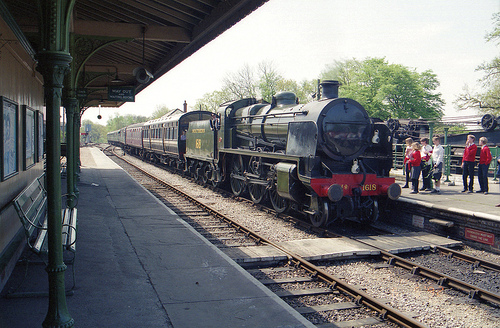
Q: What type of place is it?
A: It is a station.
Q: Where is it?
A: This is at the station.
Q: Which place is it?
A: It is a station.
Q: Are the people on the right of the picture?
A: Yes, the people are on the right of the image.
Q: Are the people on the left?
A: No, the people are on the right of the image.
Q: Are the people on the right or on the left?
A: The people are on the right of the image.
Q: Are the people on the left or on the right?
A: The people are on the right of the image.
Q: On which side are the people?
A: The people are on the right of the image.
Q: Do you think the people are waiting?
A: Yes, the people are waiting.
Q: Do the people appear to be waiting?
A: Yes, the people are waiting.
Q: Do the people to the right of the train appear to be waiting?
A: Yes, the people are waiting.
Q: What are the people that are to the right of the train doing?
A: The people are waiting.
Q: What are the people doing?
A: The people are waiting.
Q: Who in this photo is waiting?
A: The people are waiting.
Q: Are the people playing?
A: No, the people are waiting.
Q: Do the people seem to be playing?
A: No, the people are waiting.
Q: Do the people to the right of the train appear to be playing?
A: No, the people are waiting.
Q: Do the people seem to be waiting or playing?
A: The people are waiting.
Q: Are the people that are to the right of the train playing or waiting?
A: The people are waiting.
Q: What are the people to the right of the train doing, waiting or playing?
A: The people are waiting.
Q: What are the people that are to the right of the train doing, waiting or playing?
A: The people are waiting.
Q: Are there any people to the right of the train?
A: Yes, there are people to the right of the train.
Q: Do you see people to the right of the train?
A: Yes, there are people to the right of the train.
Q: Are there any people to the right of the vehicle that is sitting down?
A: Yes, there are people to the right of the train.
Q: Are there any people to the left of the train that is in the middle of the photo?
A: No, the people are to the right of the train.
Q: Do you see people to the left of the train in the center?
A: No, the people are to the right of the train.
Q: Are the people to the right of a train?
A: Yes, the people are to the right of a train.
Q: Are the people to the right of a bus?
A: No, the people are to the right of a train.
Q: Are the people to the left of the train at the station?
A: No, the people are to the right of the train.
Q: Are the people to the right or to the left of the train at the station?
A: The people are to the right of the train.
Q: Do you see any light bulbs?
A: No, there are no light bulbs.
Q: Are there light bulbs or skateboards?
A: No, there are no light bulbs or skateboards.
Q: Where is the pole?
A: The pole is at the station.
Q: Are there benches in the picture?
A: Yes, there is a bench.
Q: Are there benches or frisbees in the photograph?
A: Yes, there is a bench.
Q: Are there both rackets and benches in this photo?
A: No, there is a bench but no rackets.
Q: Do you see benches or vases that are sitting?
A: Yes, the bench is sitting.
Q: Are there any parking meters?
A: No, there are no parking meters.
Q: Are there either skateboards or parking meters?
A: No, there are no parking meters or skateboards.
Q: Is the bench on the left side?
A: Yes, the bench is on the left of the image.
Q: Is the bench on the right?
A: No, the bench is on the left of the image.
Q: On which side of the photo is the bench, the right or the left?
A: The bench is on the left of the image.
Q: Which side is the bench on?
A: The bench is on the left of the image.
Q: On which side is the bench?
A: The bench is on the left of the image.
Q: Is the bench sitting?
A: Yes, the bench is sitting.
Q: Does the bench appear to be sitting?
A: Yes, the bench is sitting.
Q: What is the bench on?
A: The bench is on the platform.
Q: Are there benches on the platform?
A: Yes, there is a bench on the platform.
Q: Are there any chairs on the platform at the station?
A: No, there is a bench on the platform.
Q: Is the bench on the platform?
A: Yes, the bench is on the platform.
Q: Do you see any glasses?
A: No, there are no glasses.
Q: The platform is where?
A: The platform is at the station.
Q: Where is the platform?
A: The platform is at the station.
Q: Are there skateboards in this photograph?
A: No, there are no skateboards.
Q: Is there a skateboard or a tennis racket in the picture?
A: No, there are no skateboards or rackets.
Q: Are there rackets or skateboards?
A: No, there are no skateboards or rackets.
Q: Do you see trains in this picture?
A: Yes, there is a train.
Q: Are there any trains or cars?
A: Yes, there is a train.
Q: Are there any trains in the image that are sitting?
A: Yes, there is a train that is sitting.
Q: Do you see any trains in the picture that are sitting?
A: Yes, there is a train that is sitting.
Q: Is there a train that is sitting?
A: Yes, there is a train that is sitting.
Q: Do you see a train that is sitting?
A: Yes, there is a train that is sitting.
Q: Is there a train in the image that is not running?
A: Yes, there is a train that is sitting.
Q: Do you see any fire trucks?
A: No, there are no fire trucks.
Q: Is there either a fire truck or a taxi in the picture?
A: No, there are no fire trucks or taxis.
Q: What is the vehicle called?
A: The vehicle is a train.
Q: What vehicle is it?
A: The vehicle is a train.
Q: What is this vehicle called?
A: This is a train.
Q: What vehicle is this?
A: This is a train.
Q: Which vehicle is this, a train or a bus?
A: This is a train.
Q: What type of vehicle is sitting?
A: The vehicle is a train.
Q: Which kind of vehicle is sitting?
A: The vehicle is a train.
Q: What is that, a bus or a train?
A: That is a train.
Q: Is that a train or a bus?
A: That is a train.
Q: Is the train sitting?
A: Yes, the train is sitting.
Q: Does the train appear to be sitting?
A: Yes, the train is sitting.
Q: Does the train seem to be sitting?
A: Yes, the train is sitting.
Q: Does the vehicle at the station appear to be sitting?
A: Yes, the train is sitting.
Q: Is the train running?
A: No, the train is sitting.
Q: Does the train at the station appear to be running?
A: No, the train is sitting.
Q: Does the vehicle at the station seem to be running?
A: No, the train is sitting.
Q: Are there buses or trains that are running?
A: No, there is a train but it is sitting.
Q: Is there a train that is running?
A: No, there is a train but it is sitting.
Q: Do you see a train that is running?
A: No, there is a train but it is sitting.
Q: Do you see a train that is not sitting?
A: No, there is a train but it is sitting.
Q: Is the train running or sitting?
A: The train is sitting.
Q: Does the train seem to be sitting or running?
A: The train is sitting.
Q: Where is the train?
A: The train is at the station.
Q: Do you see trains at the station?
A: Yes, there is a train at the station.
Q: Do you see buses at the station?
A: No, there is a train at the station.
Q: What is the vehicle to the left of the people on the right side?
A: The vehicle is a train.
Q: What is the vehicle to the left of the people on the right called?
A: The vehicle is a train.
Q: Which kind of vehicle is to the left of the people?
A: The vehicle is a train.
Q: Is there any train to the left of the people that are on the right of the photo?
A: Yes, there is a train to the left of the people.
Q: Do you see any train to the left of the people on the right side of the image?
A: Yes, there is a train to the left of the people.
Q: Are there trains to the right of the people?
A: No, the train is to the left of the people.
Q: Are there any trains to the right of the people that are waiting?
A: No, the train is to the left of the people.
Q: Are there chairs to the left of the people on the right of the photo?
A: No, there is a train to the left of the people.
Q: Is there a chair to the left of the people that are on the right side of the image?
A: No, there is a train to the left of the people.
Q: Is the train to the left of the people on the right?
A: Yes, the train is to the left of the people.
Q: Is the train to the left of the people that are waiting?
A: Yes, the train is to the left of the people.